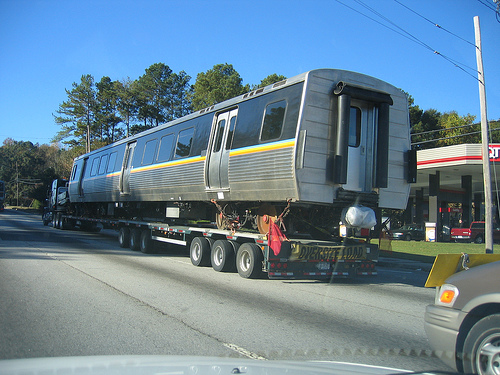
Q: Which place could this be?
A: It is a road.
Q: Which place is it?
A: It is a road.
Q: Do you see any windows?
A: Yes, there is a window.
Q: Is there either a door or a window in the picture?
A: Yes, there is a window.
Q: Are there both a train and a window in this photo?
A: Yes, there are both a window and a train.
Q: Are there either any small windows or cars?
A: Yes, there is a small window.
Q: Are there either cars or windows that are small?
A: Yes, the window is small.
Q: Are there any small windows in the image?
A: Yes, there is a small window.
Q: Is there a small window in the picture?
A: Yes, there is a small window.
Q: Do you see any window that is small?
A: Yes, there is a window that is small.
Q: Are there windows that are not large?
A: Yes, there is a small window.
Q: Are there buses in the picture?
A: No, there are no buses.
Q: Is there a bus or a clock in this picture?
A: No, there are no buses or clocks.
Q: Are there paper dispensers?
A: No, there are no paper dispensers.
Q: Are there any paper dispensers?
A: No, there are no paper dispensers.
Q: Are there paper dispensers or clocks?
A: No, there are no paper dispensers or clocks.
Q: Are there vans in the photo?
A: No, there are no vans.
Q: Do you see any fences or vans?
A: No, there are no vans or fences.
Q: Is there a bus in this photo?
A: No, there are no buses.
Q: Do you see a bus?
A: No, there are no buses.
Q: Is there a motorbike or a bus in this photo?
A: No, there are no buses or motorcycles.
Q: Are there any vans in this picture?
A: No, there are no vans.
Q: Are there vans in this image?
A: No, there are no vans.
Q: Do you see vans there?
A: No, there are no vans.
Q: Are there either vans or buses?
A: No, there are no vans or buses.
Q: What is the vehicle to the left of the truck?
A: The vehicle is a car.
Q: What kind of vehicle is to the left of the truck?
A: The vehicle is a car.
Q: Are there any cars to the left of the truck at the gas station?
A: Yes, there is a car to the left of the truck.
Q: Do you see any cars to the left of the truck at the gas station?
A: Yes, there is a car to the left of the truck.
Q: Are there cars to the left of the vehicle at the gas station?
A: Yes, there is a car to the left of the truck.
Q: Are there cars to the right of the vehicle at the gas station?
A: No, the car is to the left of the truck.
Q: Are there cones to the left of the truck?
A: No, there is a car to the left of the truck.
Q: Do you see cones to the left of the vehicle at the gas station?
A: No, there is a car to the left of the truck.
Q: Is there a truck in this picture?
A: Yes, there is a truck.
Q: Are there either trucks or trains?
A: Yes, there is a truck.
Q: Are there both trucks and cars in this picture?
A: Yes, there are both a truck and a car.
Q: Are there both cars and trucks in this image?
A: Yes, there are both a truck and a car.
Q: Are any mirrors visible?
A: No, there are no mirrors.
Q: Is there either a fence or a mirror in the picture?
A: No, there are no mirrors or fences.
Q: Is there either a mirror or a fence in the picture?
A: No, there are no mirrors or fences.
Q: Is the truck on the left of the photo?
A: No, the truck is on the right of the image.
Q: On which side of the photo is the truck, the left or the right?
A: The truck is on the right of the image.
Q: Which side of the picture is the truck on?
A: The truck is on the right of the image.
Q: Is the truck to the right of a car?
A: Yes, the truck is to the right of a car.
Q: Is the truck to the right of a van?
A: No, the truck is to the right of a car.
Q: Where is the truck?
A: The truck is at the gas station.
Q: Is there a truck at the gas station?
A: Yes, there is a truck at the gas station.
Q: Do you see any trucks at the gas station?
A: Yes, there is a truck at the gas station.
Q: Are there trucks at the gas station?
A: Yes, there is a truck at the gas station.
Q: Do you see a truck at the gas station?
A: Yes, there is a truck at the gas station.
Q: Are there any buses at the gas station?
A: No, there is a truck at the gas station.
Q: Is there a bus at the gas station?
A: No, there is a truck at the gas station.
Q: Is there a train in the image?
A: Yes, there is a train.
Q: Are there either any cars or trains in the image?
A: Yes, there is a train.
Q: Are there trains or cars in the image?
A: Yes, there is a train.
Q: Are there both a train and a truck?
A: Yes, there are both a train and a truck.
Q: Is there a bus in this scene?
A: No, there are no buses.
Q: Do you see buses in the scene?
A: No, there are no buses.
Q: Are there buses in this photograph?
A: No, there are no buses.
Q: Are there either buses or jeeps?
A: No, there are no buses or jeeps.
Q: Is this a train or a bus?
A: This is a train.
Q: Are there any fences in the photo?
A: No, there are no fences.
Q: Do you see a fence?
A: No, there are no fences.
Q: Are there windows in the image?
A: Yes, there is a window.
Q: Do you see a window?
A: Yes, there is a window.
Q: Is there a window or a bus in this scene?
A: Yes, there is a window.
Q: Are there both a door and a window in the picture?
A: Yes, there are both a window and a door.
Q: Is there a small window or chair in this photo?
A: Yes, there is a small window.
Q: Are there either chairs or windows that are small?
A: Yes, the window is small.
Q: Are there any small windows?
A: Yes, there is a small window.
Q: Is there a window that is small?
A: Yes, there is a window that is small.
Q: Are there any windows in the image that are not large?
A: Yes, there is a small window.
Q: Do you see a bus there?
A: No, there are no buses.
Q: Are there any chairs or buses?
A: No, there are no buses or chairs.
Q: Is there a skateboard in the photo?
A: No, there are no skateboards.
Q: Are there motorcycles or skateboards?
A: No, there are no skateboards or motorcycles.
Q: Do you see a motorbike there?
A: No, there are no motorcycles.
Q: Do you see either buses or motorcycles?
A: No, there are no motorcycles or buses.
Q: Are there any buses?
A: No, there are no buses.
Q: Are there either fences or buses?
A: No, there are no buses or fences.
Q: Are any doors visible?
A: Yes, there is a door.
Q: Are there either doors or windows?
A: Yes, there is a door.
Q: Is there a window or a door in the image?
A: Yes, there is a door.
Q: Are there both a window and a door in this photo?
A: Yes, there are both a door and a window.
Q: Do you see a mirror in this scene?
A: No, there are no mirrors.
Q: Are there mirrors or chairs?
A: No, there are no mirrors or chairs.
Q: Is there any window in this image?
A: Yes, there is a window.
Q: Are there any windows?
A: Yes, there is a window.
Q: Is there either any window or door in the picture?
A: Yes, there is a window.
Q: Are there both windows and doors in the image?
A: Yes, there are both a window and a door.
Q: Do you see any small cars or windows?
A: Yes, there is a small window.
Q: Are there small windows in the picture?
A: Yes, there is a small window.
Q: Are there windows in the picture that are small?
A: Yes, there is a window that is small.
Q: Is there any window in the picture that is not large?
A: Yes, there is a small window.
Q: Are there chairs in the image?
A: No, there are no chairs.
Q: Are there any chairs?
A: No, there are no chairs.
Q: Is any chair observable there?
A: No, there are no chairs.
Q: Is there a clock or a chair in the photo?
A: No, there are no chairs or clocks.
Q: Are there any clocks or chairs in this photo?
A: No, there are no chairs or clocks.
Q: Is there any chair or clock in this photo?
A: No, there are no chairs or clocks.